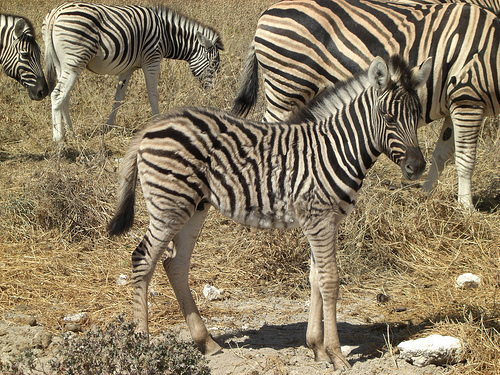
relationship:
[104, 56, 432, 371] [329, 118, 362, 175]
zebra has stripes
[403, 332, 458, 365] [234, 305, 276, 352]
rock on ground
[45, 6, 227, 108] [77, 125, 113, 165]
zebra grazing on dead grass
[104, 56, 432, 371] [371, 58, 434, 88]
zebra has perked up ears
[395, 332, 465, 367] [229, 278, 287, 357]
rock are lying on ground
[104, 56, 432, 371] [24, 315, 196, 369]
zebra s standing next to dead shrubbery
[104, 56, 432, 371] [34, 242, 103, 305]
zebra are standing on grass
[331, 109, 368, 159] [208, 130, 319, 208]
stripes are on body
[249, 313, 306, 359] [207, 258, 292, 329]
shadow on ground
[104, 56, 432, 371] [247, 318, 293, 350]
zebra has a shadow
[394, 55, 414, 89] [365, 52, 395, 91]
hair in between ears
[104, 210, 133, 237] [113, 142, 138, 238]
hair on tail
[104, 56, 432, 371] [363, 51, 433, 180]
zebra has a head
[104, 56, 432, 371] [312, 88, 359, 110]
zebra has a mane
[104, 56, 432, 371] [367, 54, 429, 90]
zebra has ears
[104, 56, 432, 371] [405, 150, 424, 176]
zebra has a nose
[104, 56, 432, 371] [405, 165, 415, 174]
zebra has a nose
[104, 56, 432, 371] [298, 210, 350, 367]
zebra has legs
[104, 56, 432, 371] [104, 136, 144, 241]
zebra has tail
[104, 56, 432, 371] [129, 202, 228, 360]
zebra has legs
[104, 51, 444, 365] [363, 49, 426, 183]
zebra has head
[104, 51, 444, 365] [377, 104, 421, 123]
zebra has eyes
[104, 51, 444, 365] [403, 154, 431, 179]
zebra has nose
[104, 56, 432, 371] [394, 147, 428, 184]
zebra has mouth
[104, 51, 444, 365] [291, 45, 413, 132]
zebra has mane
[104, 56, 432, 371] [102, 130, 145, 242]
zebra has tail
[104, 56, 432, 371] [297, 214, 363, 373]
zebra has legs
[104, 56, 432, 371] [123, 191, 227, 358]
zebra has legs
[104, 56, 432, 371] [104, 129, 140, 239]
zebra has tail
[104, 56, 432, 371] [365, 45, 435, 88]
zebra has ear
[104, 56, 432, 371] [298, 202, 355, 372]
zebra has legs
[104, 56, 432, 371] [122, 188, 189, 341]
zebra has leg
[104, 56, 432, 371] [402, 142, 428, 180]
zebra has nose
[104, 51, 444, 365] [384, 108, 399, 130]
zebra has eye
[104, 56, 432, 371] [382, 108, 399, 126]
zebra has eye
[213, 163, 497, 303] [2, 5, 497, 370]
grass lying on ground